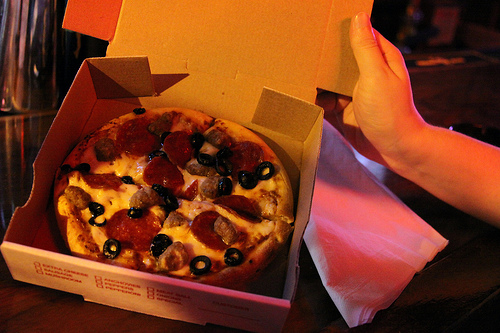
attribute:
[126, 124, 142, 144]
pepperoni — red, round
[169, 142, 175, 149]
pepperoni — red, round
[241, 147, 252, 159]
pepperoni — red, round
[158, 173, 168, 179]
pepperoni — red, round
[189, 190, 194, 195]
pepperoni — red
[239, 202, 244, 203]
pepperoni — red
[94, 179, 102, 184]
pepperoni — red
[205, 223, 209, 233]
pepperoni — red, round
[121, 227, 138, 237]
pepperoni — red, round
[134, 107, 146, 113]
olive — black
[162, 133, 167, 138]
olive — black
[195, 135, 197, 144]
olive — black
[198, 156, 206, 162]
olive — black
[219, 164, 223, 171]
olive — black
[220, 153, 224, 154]
olive — black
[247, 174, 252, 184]
olive — black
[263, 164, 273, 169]
olive — black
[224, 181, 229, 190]
olive — black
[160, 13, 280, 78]
box — browm